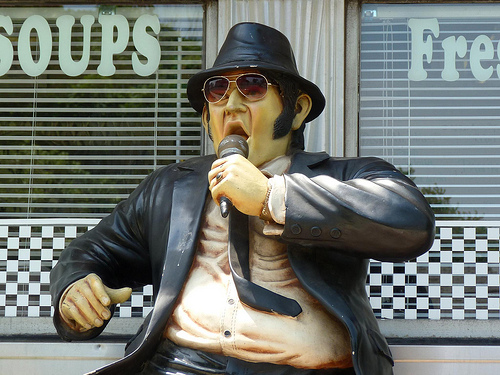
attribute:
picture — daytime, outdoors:
[0, 0, 499, 375]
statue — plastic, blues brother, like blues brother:
[48, 22, 439, 374]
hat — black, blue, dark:
[186, 21, 327, 124]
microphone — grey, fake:
[217, 135, 250, 218]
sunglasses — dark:
[196, 72, 280, 104]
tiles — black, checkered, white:
[0, 218, 499, 322]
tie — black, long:
[226, 203, 305, 318]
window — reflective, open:
[1, 1, 206, 226]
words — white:
[0, 14, 166, 77]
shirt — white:
[159, 151, 356, 370]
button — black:
[223, 328, 233, 338]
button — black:
[288, 222, 303, 240]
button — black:
[308, 226, 325, 241]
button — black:
[330, 224, 341, 241]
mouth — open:
[221, 118, 251, 144]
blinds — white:
[0, 17, 204, 219]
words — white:
[406, 16, 499, 85]